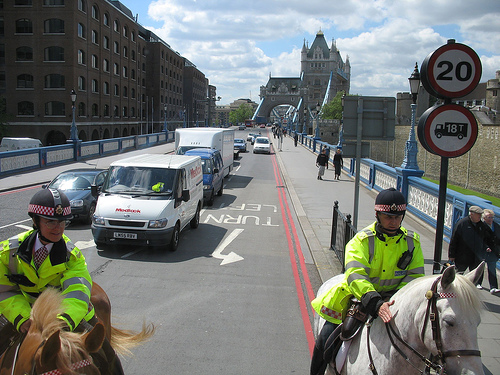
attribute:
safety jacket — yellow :
[340, 220, 428, 320]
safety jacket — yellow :
[4, 228, 98, 332]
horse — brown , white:
[304, 253, 489, 374]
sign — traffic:
[394, 35, 491, 173]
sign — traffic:
[413, 32, 479, 176]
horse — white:
[312, 259, 492, 371]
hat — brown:
[463, 201, 489, 214]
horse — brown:
[1, 172, 118, 367]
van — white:
[99, 156, 209, 250]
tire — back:
[190, 204, 204, 230]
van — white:
[90, 151, 205, 253]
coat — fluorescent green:
[0, 231, 112, 341]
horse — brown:
[4, 269, 129, 374]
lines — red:
[265, 149, 318, 350]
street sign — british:
[404, 37, 494, 339]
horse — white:
[279, 224, 494, 374]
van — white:
[84, 150, 206, 257]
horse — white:
[428, 269, 448, 342]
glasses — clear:
[30, 214, 71, 227]